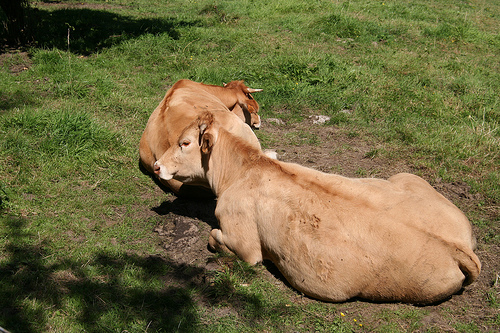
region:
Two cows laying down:
[105, 35, 461, 320]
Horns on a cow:
[211, 72, 272, 100]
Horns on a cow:
[181, 116, 213, 140]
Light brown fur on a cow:
[275, 189, 365, 254]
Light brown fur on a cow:
[173, 95, 232, 120]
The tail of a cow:
[446, 235, 485, 279]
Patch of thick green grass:
[318, 9, 399, 44]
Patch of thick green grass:
[425, 13, 481, 40]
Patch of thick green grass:
[276, 42, 356, 93]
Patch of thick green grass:
[34, 110, 99, 165]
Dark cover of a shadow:
[0, 0, 197, 62]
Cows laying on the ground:
[132, 76, 480, 307]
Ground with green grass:
[272, 20, 494, 145]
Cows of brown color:
[133, 76, 484, 307]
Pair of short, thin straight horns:
[216, 73, 266, 99]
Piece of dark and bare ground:
[159, 214, 202, 251]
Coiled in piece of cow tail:
[450, 239, 485, 298]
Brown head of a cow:
[148, 110, 218, 190]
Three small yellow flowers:
[333, 309, 371, 330]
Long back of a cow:
[254, 151, 451, 250]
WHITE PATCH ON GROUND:
[309, 111, 334, 127]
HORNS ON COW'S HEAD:
[220, 79, 264, 94]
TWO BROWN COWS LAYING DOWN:
[137, 75, 480, 306]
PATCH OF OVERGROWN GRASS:
[24, 112, 97, 162]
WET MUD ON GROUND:
[159, 208, 204, 255]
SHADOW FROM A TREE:
[1, 0, 202, 55]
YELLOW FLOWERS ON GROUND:
[336, 311, 367, 328]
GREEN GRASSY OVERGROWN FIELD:
[246, 9, 491, 75]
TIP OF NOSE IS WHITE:
[151, 159, 174, 182]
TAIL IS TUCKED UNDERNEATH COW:
[441, 237, 486, 287]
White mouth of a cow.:
[150, 159, 177, 186]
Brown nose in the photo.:
[151, 163, 160, 178]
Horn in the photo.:
[243, 85, 262, 98]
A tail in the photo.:
[460, 245, 487, 281]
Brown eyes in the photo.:
[177, 139, 193, 153]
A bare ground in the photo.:
[320, 133, 355, 164]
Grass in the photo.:
[57, 281, 128, 323]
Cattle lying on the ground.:
[134, 71, 484, 301]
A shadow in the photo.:
[57, 15, 144, 46]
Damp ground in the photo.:
[167, 216, 190, 242]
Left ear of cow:
[197, 127, 221, 154]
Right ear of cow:
[226, 101, 249, 124]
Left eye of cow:
[175, 135, 195, 150]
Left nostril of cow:
[152, 165, 160, 175]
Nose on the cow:
[149, 159, 174, 183]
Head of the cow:
[135, 110, 217, 185]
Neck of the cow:
[207, 121, 264, 198]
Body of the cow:
[215, 156, 477, 309]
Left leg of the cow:
[197, 211, 270, 269]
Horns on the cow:
[219, 74, 266, 102]